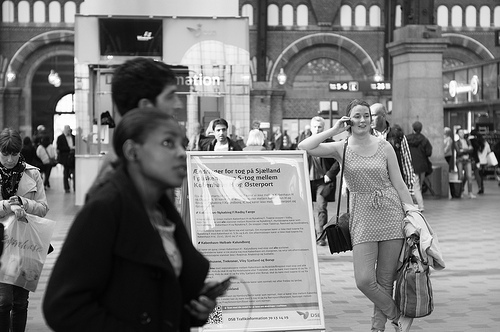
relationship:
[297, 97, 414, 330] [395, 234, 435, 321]
woman holding bag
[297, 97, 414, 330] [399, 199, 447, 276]
person holding coat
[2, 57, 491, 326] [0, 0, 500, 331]
people at station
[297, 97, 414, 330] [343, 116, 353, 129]
woman talking on cell phone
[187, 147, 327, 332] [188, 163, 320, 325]
sign has reading information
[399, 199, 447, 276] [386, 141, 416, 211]
jacket hanging on arm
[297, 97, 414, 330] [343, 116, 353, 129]
woman holding cell phone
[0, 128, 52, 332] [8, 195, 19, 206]
woman looking at watch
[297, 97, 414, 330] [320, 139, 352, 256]
woman with bag on shoulder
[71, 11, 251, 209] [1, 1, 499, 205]
information booth in background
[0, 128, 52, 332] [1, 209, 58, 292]
woman holding shopping bag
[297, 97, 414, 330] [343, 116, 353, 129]
lady talking on cell phone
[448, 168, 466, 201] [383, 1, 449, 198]
trash receptacle next to pillar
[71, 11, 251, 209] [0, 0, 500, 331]
information counter at station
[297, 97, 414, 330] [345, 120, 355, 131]
woman on phone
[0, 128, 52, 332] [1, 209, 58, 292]
woman with shopping bag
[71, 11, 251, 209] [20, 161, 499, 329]
information sign on ground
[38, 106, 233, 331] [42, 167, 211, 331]
people wearing coat